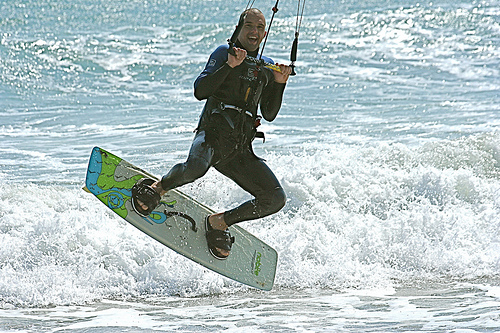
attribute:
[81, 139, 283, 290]
board — white, blue, green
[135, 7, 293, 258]
man — wakeboarding, smiling, bald, kitesurfing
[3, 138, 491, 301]
waves — crashing, foamy, white, splashing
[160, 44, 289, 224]
wetsuit — black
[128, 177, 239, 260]
feet — bare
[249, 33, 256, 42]
smile — big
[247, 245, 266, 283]
brand name — green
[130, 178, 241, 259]
footstraps — black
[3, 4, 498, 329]
water — nice, blue, reflecting, light, everywhere, shiney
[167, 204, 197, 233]
handle — black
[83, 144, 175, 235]
decorations — green, blue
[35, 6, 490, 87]
foam — white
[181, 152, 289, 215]
knees — bent